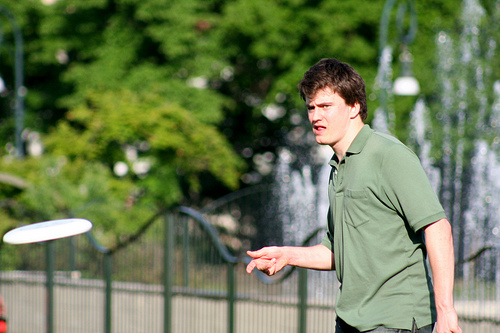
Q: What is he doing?
A: Walking.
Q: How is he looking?
A: Normal.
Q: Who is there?
A: Young man.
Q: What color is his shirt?
A: Green.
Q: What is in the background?
A: Trees.